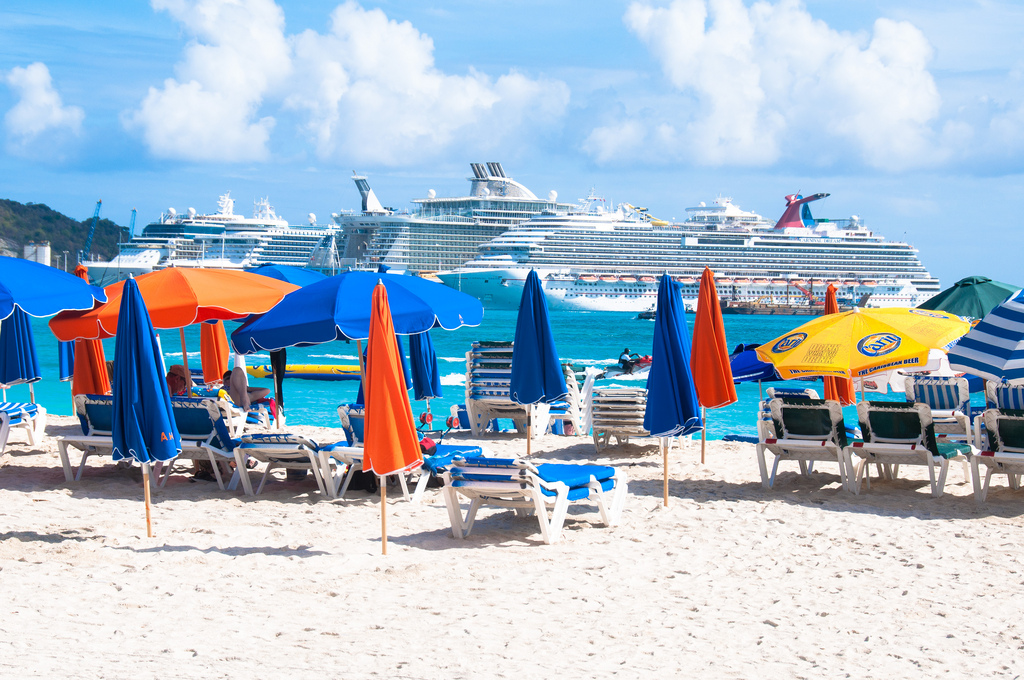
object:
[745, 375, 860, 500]
chair outside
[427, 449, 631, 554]
chair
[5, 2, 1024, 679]
outside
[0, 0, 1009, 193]
blue sky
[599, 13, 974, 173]
clouds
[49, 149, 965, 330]
large ship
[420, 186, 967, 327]
white ship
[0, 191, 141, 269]
green hill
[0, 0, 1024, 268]
background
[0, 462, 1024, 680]
white sand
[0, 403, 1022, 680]
colored sand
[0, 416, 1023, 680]
sand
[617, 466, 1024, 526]
shadow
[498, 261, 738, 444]
three umbrellas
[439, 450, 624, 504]
blue cushions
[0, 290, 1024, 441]
blue water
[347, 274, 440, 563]
large umbrella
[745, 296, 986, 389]
open umbrella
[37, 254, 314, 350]
open umbrella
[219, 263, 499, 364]
open umbrella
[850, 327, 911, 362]
symbols